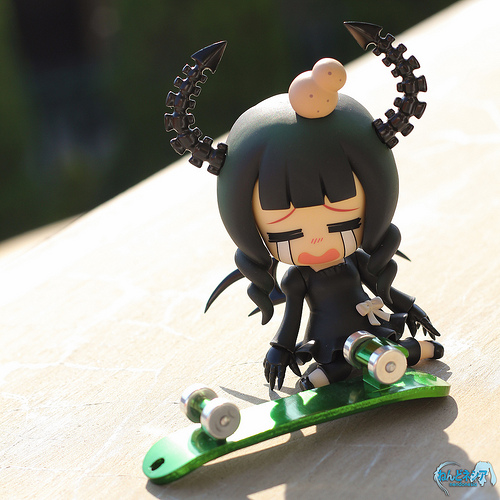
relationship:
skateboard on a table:
[141, 333, 450, 478] [0, 1, 499, 499]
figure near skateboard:
[162, 20, 444, 390] [141, 333, 450, 478]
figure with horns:
[162, 20, 444, 390] [163, 20, 427, 178]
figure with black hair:
[162, 20, 444, 390] [216, 91, 402, 325]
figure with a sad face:
[162, 20, 444, 390] [249, 170, 367, 266]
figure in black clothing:
[162, 20, 444, 390] [261, 253, 446, 390]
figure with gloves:
[162, 20, 444, 390] [255, 343, 301, 391]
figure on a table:
[162, 20, 444, 390] [0, 1, 499, 499]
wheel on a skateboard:
[199, 398, 241, 440] [141, 333, 450, 478]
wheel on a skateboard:
[178, 381, 217, 423] [141, 333, 450, 478]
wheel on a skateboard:
[371, 344, 406, 382] [141, 333, 450, 478]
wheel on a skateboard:
[344, 326, 377, 369] [141, 333, 450, 478]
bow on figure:
[355, 296, 392, 328] [162, 20, 444, 390]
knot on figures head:
[290, 58, 346, 119] [216, 92, 397, 269]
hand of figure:
[405, 302, 440, 340] [162, 20, 444, 390]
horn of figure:
[163, 38, 228, 174] [162, 20, 444, 390]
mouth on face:
[298, 249, 340, 266] [249, 170, 367, 266]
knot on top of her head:
[290, 58, 346, 119] [216, 92, 397, 269]